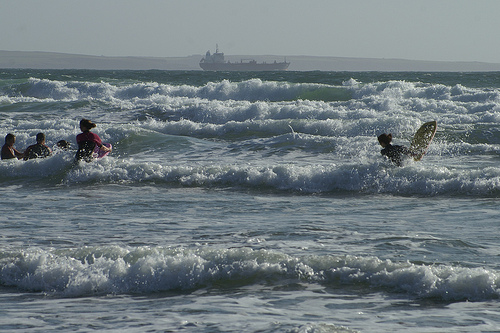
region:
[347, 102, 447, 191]
person on a boogie board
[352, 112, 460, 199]
person on a surfboard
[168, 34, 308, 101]
a large freight ship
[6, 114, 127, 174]
people playing in water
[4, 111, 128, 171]
people playing in ocean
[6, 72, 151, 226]
people riding the waves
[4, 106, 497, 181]
people playing in water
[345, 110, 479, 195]
surfer rides a wave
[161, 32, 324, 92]
a ship sails the ocean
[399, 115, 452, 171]
a yellow boogie board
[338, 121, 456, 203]
woman on boogie board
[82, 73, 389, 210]
waves rolling in to shore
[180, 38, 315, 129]
large tanker in distance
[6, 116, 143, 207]
group playing in waves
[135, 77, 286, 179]
dark waves cresting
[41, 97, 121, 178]
woman on pink boogie board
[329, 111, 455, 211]
white ocean spray around board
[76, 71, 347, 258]
choppy ocean waves crashing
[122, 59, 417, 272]
angry looking ocean waves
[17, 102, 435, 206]
people getting wet in ocean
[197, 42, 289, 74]
Ship in the distance of the ocean.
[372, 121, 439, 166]
A woman surfing on the right.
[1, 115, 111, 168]
Group of three people on the left.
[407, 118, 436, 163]
Surfboard a woman is on in the water.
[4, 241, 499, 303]
Small thin waves in the ocean.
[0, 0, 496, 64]
Hazy gray sky in the distance.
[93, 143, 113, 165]
Small part of a surfboard to the left.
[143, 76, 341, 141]
Three sets of waves in the water.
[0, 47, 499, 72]
Hills in the background.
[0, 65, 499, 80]
Calmer water in the distance.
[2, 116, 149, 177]
group of people in the water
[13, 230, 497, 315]
long and thin wave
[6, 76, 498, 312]
restless water with several big waves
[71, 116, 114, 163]
person standing in the water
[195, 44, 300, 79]
ship in the distance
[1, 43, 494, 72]
land far off in the distance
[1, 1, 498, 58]
clear skies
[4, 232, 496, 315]
wave rolling into shore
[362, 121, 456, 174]
playing in the water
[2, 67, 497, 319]
rough seas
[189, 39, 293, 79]
Ship in far background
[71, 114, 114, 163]
Woman on pink surfboard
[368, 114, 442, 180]
Woman holding yellow surfboard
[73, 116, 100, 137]
Ponytail in woman's hair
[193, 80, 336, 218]
White wave on water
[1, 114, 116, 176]
Four people in water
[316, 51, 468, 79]
Hills in far background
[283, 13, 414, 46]
gloomy gray sky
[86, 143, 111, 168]
Pink surfboard under woman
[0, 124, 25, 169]
Man half submerged in water